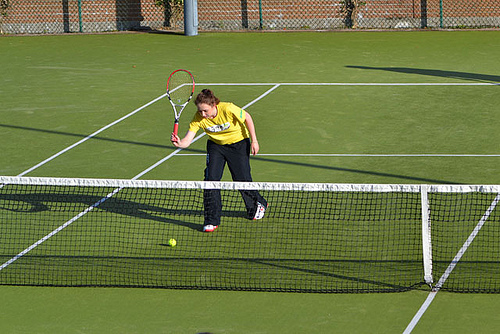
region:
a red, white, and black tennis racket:
[166, 65, 193, 133]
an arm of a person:
[246, 107, 261, 139]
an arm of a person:
[178, 119, 200, 150]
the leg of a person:
[229, 155, 257, 211]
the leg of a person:
[196, 157, 221, 224]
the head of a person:
[193, 89, 225, 119]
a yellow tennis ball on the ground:
[162, 232, 184, 252]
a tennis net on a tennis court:
[44, 166, 136, 298]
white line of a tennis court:
[288, 71, 381, 89]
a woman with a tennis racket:
[157, 61, 264, 179]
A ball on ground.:
[163, 234, 175, 249]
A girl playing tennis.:
[155, 79, 274, 222]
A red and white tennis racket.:
[162, 63, 201, 156]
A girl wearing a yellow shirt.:
[181, 92, 263, 153]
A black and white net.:
[2, 171, 498, 299]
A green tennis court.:
[2, 34, 489, 332]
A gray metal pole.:
[181, 4, 203, 33]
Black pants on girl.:
[198, 137, 269, 219]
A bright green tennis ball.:
[163, 233, 178, 248]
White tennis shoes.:
[193, 202, 274, 232]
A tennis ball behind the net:
[162, 227, 190, 254]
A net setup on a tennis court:
[281, 153, 460, 300]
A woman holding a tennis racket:
[165, 62, 260, 174]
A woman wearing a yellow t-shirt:
[181, 88, 258, 158]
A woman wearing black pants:
[183, 132, 267, 179]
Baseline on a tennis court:
[285, 47, 495, 122]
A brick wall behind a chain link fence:
[235, 2, 433, 36]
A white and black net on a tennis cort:
[16, 169, 398, 311]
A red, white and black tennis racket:
[163, 62, 197, 139]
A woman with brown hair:
[193, 85, 229, 123]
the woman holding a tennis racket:
[161, 61, 283, 223]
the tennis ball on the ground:
[167, 235, 184, 247]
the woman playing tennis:
[143, 51, 275, 231]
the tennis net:
[1, 165, 496, 310]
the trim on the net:
[15, 174, 443, 192]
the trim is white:
[1, 175, 434, 192]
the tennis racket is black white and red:
[155, 48, 214, 165]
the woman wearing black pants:
[197, 134, 288, 216]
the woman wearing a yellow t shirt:
[188, 102, 273, 144]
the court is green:
[313, 84, 405, 131]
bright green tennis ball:
[152, 229, 202, 257]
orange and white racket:
[145, 57, 203, 148]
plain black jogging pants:
[193, 131, 278, 221]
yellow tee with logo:
[181, 97, 256, 156]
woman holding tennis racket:
[151, 53, 295, 256]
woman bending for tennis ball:
[133, 52, 300, 259]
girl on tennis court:
[11, 6, 493, 326]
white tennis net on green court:
[4, 162, 499, 319]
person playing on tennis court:
[6, 1, 493, 328]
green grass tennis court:
[3, 2, 499, 328]